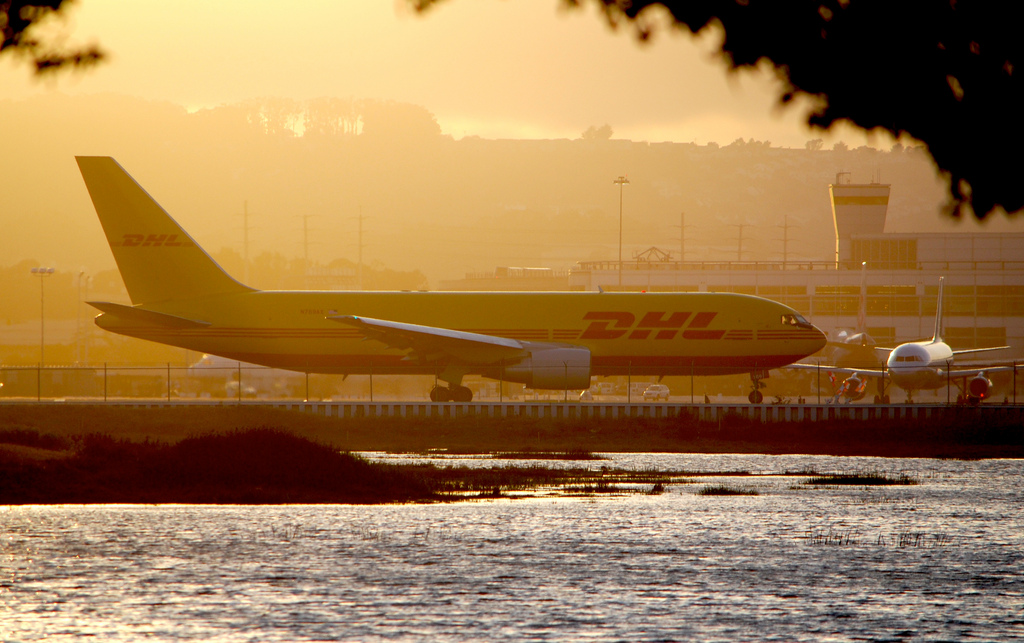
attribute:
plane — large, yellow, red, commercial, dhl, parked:
[70, 146, 830, 410]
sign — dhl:
[573, 306, 727, 350]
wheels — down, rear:
[425, 379, 478, 404]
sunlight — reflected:
[21, 486, 1024, 545]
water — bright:
[3, 439, 1024, 639]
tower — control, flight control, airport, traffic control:
[821, 170, 899, 269]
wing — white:
[330, 308, 527, 366]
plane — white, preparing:
[787, 263, 1024, 409]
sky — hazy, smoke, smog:
[3, 2, 1024, 180]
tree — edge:
[571, 3, 1024, 228]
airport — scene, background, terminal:
[2, 172, 1024, 444]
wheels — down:
[745, 385, 766, 407]